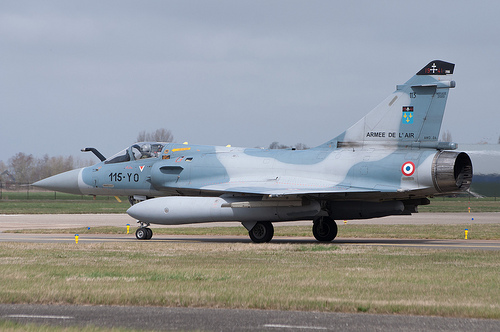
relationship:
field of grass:
[1, 190, 484, 313] [1, 244, 498, 314]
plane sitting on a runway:
[31, 57, 471, 241] [0, 227, 484, 254]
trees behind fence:
[0, 120, 498, 200] [1, 170, 498, 207]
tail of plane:
[325, 56, 457, 146] [31, 38, 498, 328]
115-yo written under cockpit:
[108, 171, 138, 182] [104, 141, 160, 166]